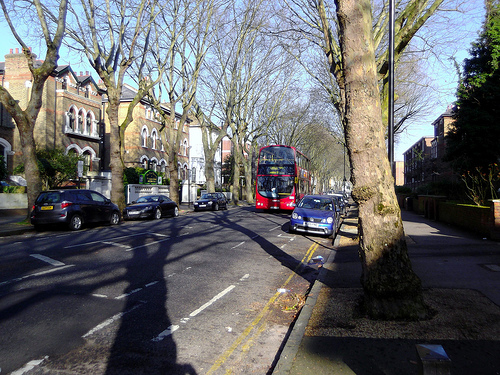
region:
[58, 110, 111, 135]
three arched windows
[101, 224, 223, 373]
tree shadow on the road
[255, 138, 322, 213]
double decker bus in the road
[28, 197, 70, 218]
gold license plate on the car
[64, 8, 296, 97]
trees don't have any leaves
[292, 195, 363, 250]
blue car parked along road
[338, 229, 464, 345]
tree planted in the sidewalk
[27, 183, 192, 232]
parked cars facing each other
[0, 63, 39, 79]
red stripes on the building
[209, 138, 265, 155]
white stripe o building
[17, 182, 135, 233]
black vehicle with yellow plate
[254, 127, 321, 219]
red double decker bus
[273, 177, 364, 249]
blue car parked by curb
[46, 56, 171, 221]
big tree along roadway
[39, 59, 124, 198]
white framed windows on building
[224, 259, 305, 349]
yellow lines painted on road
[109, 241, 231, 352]
white lines painted on road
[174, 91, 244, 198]
white building behind tree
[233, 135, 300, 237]
red bus with headlights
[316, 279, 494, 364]
gravel patch around tree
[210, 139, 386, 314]
the bus is tall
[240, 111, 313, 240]
the bus is tall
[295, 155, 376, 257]
the bus is tall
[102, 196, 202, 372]
long shadow of tree cast on street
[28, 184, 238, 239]
cars parked on side of street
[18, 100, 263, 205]
brick building lining street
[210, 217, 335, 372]
yellow lines on side of street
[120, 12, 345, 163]
trees with no leaves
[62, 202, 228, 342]
white lines painted on street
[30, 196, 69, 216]
yellow plate on back of car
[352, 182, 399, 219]
moss growing on tree trunk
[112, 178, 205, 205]
white wooden fence in front of building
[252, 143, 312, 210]
A red double decker bus.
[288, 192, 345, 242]
A blue car sitting on the right side of the road.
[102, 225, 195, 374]
A large tree trunk going across the road.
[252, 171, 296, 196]
Large front windshield on a double decker bus.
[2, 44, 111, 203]
First building on the left.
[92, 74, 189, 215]
Second building from the left with many arched windows.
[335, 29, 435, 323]
Large tree trunk on the right that leans to the left.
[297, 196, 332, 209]
Windshield of a blue car on the right.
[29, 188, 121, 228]
A dark gray mini van on the left side of the road.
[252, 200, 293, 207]
Two headlights on the front of a double decker